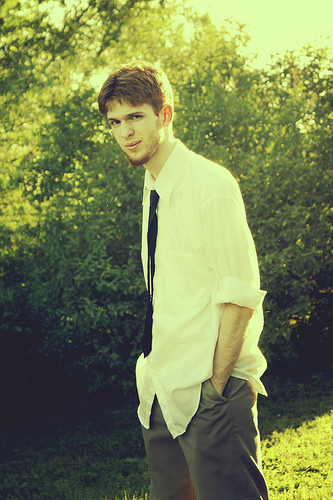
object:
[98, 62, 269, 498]
guy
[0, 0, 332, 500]
garden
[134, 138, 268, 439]
t-shirt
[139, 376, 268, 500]
pants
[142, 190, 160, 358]
tie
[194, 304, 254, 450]
hands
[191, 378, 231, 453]
pockets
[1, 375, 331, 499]
grass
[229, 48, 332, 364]
bush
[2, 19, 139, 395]
bush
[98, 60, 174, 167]
head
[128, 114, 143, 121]
eye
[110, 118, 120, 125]
eye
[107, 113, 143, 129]
intense look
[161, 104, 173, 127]
ear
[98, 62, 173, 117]
hair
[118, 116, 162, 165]
beard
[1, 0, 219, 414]
tree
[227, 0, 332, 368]
tree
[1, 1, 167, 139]
leaves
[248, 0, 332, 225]
leaves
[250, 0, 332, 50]
sun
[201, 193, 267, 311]
sleeve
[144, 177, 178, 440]
buttons